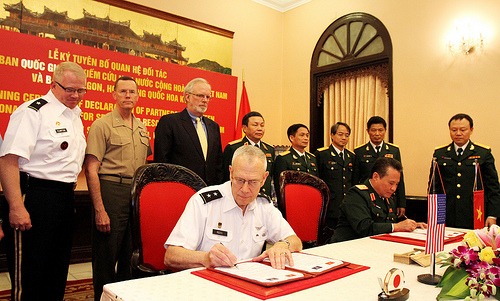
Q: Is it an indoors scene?
A: Yes, it is indoors.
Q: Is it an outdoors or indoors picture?
A: It is indoors.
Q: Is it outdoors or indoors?
A: It is indoors.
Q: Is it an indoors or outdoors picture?
A: It is indoors.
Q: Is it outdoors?
A: No, it is indoors.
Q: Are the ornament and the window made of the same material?
A: Yes, both the ornament and the window are made of glass.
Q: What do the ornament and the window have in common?
A: The material, both the ornament and the window are glass.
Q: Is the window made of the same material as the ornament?
A: Yes, both the window and the ornament are made of glass.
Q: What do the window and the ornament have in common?
A: The material, both the window and the ornament are glass.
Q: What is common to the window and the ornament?
A: The material, both the window and the ornament are glass.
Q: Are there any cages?
A: No, there are no cages.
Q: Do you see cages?
A: No, there are no cages.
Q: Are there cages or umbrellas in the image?
A: No, there are no cages or umbrellas.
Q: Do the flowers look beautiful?
A: Yes, the flowers are beautiful.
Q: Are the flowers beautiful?
A: Yes, the flowers are beautiful.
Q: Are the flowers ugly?
A: No, the flowers are beautiful.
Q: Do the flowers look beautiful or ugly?
A: The flowers are beautiful.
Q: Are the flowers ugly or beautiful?
A: The flowers are beautiful.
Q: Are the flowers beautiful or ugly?
A: The flowers are beautiful.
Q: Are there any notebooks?
A: No, there are no notebooks.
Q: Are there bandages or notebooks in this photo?
A: No, there are no notebooks or bandages.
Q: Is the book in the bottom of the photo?
A: Yes, the book is in the bottom of the image.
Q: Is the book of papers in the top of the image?
A: No, the book is in the bottom of the image.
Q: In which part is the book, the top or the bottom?
A: The book is in the bottom of the image.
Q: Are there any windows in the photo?
A: Yes, there is a window.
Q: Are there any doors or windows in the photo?
A: Yes, there is a window.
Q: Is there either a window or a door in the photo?
A: Yes, there is a window.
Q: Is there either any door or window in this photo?
A: Yes, there is a window.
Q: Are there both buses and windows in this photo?
A: No, there is a window but no buses.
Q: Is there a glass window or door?
A: Yes, there is a glass window.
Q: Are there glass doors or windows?
A: Yes, there is a glass window.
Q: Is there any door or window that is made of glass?
A: Yes, the window is made of glass.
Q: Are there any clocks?
A: No, there are no clocks.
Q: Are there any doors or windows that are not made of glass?
A: No, there is a window but it is made of glass.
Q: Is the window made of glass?
A: Yes, the window is made of glass.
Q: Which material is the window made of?
A: The window is made of glass.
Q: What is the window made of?
A: The window is made of glass.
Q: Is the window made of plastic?
A: No, the window is made of glass.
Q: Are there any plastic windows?
A: No, there is a window but it is made of glass.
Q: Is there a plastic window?
A: No, there is a window but it is made of glass.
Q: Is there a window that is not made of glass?
A: No, there is a window but it is made of glass.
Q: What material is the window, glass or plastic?
A: The window is made of glass.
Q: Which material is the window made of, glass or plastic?
A: The window is made of glass.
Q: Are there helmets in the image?
A: No, there are no helmets.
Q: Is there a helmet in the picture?
A: No, there are no helmets.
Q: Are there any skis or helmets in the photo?
A: No, there are no helmets or skis.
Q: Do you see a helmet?
A: No, there are no helmets.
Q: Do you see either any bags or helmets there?
A: No, there are no helmets or bags.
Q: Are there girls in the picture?
A: No, there are no girls.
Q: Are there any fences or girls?
A: No, there are no girls or fences.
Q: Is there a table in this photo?
A: Yes, there is a table.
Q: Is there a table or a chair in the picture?
A: Yes, there is a table.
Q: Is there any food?
A: No, there is no food.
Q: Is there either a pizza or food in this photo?
A: No, there are no food or pizzas.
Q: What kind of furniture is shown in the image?
A: The furniture is a table.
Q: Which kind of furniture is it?
A: The piece of furniture is a table.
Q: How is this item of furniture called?
A: This is a table.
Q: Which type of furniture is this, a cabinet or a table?
A: This is a table.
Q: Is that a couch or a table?
A: That is a table.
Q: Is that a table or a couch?
A: That is a table.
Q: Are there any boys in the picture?
A: No, there are no boys.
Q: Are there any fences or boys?
A: No, there are no boys or fences.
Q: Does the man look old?
A: Yes, the man is old.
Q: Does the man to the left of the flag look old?
A: Yes, the man is old.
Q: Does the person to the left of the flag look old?
A: Yes, the man is old.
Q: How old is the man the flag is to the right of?
A: The man is old.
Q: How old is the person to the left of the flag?
A: The man is old.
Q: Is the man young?
A: No, the man is old.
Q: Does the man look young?
A: No, the man is old.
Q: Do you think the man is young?
A: No, the man is old.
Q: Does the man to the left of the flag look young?
A: No, the man is old.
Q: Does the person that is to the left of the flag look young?
A: No, the man is old.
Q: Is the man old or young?
A: The man is old.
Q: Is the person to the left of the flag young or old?
A: The man is old.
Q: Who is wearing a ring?
A: The man is wearing a ring.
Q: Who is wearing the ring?
A: The man is wearing a ring.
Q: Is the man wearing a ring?
A: Yes, the man is wearing a ring.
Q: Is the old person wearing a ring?
A: Yes, the man is wearing a ring.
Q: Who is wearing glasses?
A: The man is wearing glasses.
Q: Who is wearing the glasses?
A: The man is wearing glasses.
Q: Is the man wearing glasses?
A: Yes, the man is wearing glasses.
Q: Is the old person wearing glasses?
A: Yes, the man is wearing glasses.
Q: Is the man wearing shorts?
A: No, the man is wearing glasses.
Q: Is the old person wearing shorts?
A: No, the man is wearing glasses.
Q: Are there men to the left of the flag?
A: Yes, there is a man to the left of the flag.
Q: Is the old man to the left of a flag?
A: Yes, the man is to the left of a flag.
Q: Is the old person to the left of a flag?
A: Yes, the man is to the left of a flag.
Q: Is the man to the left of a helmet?
A: No, the man is to the left of a flag.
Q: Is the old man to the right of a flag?
A: No, the man is to the left of a flag.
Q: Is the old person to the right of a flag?
A: No, the man is to the left of a flag.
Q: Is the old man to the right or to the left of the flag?
A: The man is to the left of the flag.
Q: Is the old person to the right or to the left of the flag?
A: The man is to the left of the flag.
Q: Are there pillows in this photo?
A: No, there are no pillows.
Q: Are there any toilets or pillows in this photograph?
A: No, there are no pillows or toilets.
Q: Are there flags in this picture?
A: Yes, there is a flag.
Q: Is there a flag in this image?
A: Yes, there is a flag.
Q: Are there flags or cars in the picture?
A: Yes, there is a flag.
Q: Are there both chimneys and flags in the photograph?
A: No, there is a flag but no chimneys.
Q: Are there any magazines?
A: No, there are no magazines.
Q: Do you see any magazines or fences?
A: No, there are no magazines or fences.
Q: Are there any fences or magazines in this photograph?
A: No, there are no magazines or fences.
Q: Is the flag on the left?
A: No, the flag is on the right of the image.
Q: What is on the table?
A: The flag is on the table.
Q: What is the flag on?
A: The flag is on the table.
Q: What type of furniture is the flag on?
A: The flag is on the table.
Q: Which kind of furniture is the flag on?
A: The flag is on the table.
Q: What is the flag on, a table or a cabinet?
A: The flag is on a table.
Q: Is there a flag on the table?
A: Yes, there is a flag on the table.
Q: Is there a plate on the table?
A: No, there is a flag on the table.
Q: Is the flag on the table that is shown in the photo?
A: Yes, the flag is on the table.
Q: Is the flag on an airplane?
A: No, the flag is on the table.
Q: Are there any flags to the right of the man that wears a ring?
A: Yes, there is a flag to the right of the man.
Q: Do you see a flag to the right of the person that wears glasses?
A: Yes, there is a flag to the right of the man.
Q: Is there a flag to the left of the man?
A: No, the flag is to the right of the man.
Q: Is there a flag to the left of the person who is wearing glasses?
A: No, the flag is to the right of the man.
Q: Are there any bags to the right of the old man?
A: No, there is a flag to the right of the man.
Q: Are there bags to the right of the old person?
A: No, there is a flag to the right of the man.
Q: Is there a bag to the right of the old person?
A: No, there is a flag to the right of the man.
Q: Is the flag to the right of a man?
A: Yes, the flag is to the right of a man.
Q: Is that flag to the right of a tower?
A: No, the flag is to the right of a man.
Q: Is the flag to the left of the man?
A: No, the flag is to the right of the man.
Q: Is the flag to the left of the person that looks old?
A: No, the flag is to the right of the man.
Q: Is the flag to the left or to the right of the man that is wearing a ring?
A: The flag is to the right of the man.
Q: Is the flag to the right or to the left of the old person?
A: The flag is to the right of the man.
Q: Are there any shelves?
A: No, there are no shelves.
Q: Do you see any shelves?
A: No, there are no shelves.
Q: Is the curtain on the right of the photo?
A: Yes, the curtain is on the right of the image.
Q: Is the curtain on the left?
A: No, the curtain is on the right of the image.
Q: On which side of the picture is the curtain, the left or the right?
A: The curtain is on the right of the image.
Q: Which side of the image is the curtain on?
A: The curtain is on the right of the image.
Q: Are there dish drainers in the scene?
A: No, there are no dish drainers.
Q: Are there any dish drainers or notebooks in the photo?
A: No, there are no dish drainers or notebooks.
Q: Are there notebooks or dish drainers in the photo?
A: No, there are no dish drainers or notebooks.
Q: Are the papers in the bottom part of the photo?
A: Yes, the papers are in the bottom of the image.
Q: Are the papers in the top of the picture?
A: No, the papers are in the bottom of the image.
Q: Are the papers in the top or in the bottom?
A: The papers are in the bottom of the image.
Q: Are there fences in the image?
A: No, there are no fences.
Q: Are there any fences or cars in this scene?
A: No, there are no fences or cars.